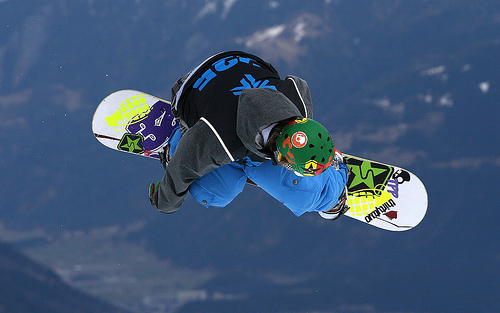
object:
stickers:
[303, 145, 304, 146]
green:
[295, 150, 308, 157]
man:
[144, 46, 356, 223]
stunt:
[141, 47, 355, 223]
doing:
[147, 50, 353, 223]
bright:
[220, 176, 233, 185]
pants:
[166, 129, 355, 220]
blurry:
[52, 22, 170, 81]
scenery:
[23, 8, 105, 60]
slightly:
[344, 0, 499, 96]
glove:
[145, 179, 178, 216]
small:
[201, 199, 209, 206]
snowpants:
[162, 128, 351, 223]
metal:
[292, 179, 299, 185]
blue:
[271, 180, 293, 192]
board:
[87, 86, 431, 234]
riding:
[123, 46, 364, 224]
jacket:
[146, 44, 319, 218]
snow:
[340, 156, 422, 232]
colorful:
[329, 151, 418, 232]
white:
[95, 123, 108, 133]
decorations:
[94, 132, 147, 154]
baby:
[139, 46, 342, 218]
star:
[119, 135, 144, 154]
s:
[346, 160, 388, 190]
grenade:
[335, 185, 394, 218]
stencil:
[343, 192, 376, 208]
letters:
[385, 177, 400, 199]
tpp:
[383, 175, 402, 200]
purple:
[386, 177, 400, 199]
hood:
[233, 85, 307, 160]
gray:
[233, 86, 304, 163]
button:
[291, 179, 300, 186]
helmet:
[269, 115, 340, 179]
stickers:
[390, 168, 412, 185]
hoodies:
[145, 46, 318, 216]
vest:
[166, 50, 310, 162]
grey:
[167, 49, 311, 163]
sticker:
[288, 130, 310, 150]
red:
[281, 135, 294, 150]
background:
[0, 191, 224, 313]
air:
[64, 31, 431, 247]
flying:
[81, 43, 436, 243]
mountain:
[0, 2, 282, 223]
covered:
[2, 0, 111, 313]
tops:
[29, 65, 92, 102]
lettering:
[188, 53, 266, 92]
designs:
[97, 95, 419, 231]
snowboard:
[85, 86, 421, 234]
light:
[163, 128, 353, 220]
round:
[289, 130, 310, 149]